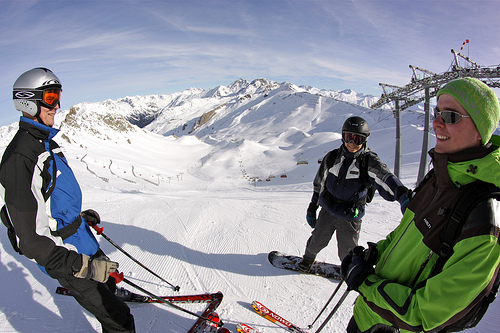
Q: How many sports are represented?
A: 2.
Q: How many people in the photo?
A: 3.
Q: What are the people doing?
A: Skiing.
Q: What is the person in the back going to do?
A: Snowboard.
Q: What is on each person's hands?
A: Gloves.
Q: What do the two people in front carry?
A: Ski poles.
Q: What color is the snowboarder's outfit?
A: Black and gray.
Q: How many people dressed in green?
A: 1.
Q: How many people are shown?
A: 3.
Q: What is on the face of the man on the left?
A: Goggles.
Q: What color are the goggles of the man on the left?
A: Orange.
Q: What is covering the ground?
A: Snow.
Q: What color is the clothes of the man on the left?
A: Blue, black, and white.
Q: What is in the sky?
A: Clouds.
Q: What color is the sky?
A: Blue.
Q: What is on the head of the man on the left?
A: Helmet.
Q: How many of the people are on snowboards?
A: 1.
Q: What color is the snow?
A: White.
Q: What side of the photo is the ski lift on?
A: Right.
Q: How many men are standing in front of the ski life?
A: 2.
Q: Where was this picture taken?
A: Mountains.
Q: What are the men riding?
A: Skis.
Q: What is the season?
A: Winter.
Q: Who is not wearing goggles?
A: The man in green.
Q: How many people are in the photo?
A: 3.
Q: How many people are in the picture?
A: 3.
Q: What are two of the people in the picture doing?
A: Skiing.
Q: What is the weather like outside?
A: Cold.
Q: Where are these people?
A: Ski resort.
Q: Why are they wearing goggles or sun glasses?
A: Because it is bright.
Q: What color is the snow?
A: White.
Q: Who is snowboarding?
A: The lady in black.